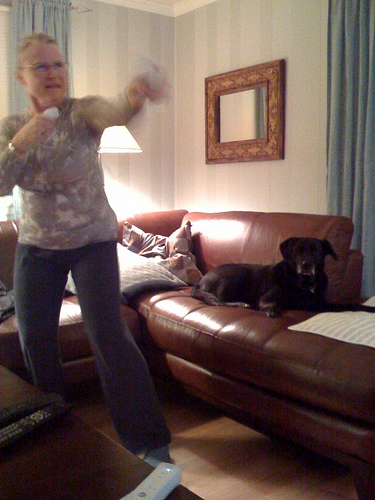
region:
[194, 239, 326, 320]
black dog sitting on the couch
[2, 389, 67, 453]
two black remote controls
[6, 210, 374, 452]
brown sectional couch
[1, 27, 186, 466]
woman playing video game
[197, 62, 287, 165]
mirror on the wall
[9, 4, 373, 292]
blue curtains by the windows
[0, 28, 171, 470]
woman wearing glasses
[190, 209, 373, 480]
black dog on couch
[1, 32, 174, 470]
Woman holding game remotes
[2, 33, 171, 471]
Woman with blonde hair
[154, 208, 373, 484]
Black dog lying on brown couch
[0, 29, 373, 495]
Woman standing next to brown couch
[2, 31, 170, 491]
Woman wearing jeans and shirt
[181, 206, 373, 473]
Black dog lying on large leather couch.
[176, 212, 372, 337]
black dog laying on couch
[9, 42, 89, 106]
lady wearing glasses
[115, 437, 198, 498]
white video game controller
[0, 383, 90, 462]
black remotes on table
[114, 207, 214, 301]
throw pillows on chair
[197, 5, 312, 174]
framed mirror on the wall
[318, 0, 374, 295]
blue curtains hanging in living room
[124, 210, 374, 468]
brown leather couch in living room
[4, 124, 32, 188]
lady wearing watch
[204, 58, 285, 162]
brown framed wall mirror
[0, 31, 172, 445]
older lady playing with Wii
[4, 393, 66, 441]
black remote controls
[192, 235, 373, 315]
black dog on couch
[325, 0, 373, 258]
long blue curtain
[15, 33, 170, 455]
lady is wearing dark colored pants and floral shirt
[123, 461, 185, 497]
wii controller on table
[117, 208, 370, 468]
brown leather couch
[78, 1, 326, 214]
light blue striped wallpaper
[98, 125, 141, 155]
lit up lamp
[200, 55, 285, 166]
mirror with decorative frame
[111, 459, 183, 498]
operating white controller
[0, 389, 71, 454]
two black television remotes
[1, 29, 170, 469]
woman wearing dark pants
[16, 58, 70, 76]
thin metal framed glasses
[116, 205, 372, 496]
dog laying on a leather couch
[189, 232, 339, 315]
large black dog laying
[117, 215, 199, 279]
brown and white checkered pillow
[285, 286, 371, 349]
white striped towel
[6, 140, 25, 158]
shiny watch around wrist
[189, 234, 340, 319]
large black dog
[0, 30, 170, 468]
older woman holding Wii controller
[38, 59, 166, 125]
white video game controller